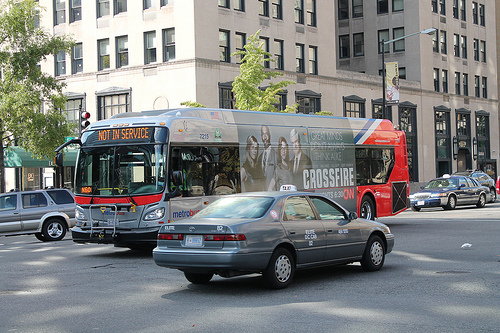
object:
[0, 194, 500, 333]
street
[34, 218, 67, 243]
tire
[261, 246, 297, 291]
tire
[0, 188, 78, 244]
vehicle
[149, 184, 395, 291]
car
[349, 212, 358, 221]
mirror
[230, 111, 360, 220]
ad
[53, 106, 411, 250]
bus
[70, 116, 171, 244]
front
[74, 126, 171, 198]
windshield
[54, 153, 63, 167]
mirror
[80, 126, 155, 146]
sign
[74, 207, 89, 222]
headlight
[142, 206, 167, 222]
headlight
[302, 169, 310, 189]
letters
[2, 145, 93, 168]
awning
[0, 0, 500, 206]
building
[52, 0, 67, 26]
window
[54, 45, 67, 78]
window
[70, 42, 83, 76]
window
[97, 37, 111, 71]
window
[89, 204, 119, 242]
rack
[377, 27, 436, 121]
streetlamp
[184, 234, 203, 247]
license plate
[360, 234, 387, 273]
tire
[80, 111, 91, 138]
light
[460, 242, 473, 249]
paper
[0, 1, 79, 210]
tree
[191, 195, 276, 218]
windshield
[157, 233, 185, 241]
brake light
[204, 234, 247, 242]
brake light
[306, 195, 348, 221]
window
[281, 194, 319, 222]
window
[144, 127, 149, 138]
letters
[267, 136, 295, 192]
people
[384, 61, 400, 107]
banner